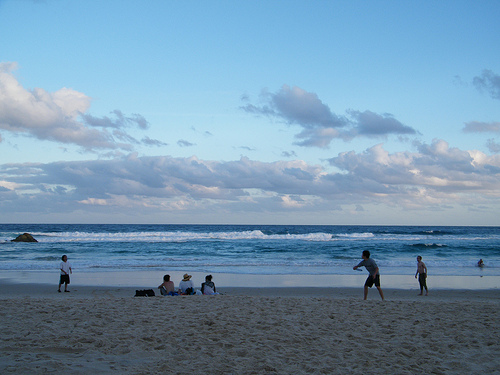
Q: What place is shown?
A: It is a beach.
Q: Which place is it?
A: It is a beach.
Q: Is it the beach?
A: Yes, it is the beach.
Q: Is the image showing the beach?
A: Yes, it is showing the beach.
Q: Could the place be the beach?
A: Yes, it is the beach.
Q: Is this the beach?
A: Yes, it is the beach.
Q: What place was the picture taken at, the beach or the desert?
A: It was taken at the beach.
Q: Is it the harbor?
A: No, it is the beach.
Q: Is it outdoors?
A: Yes, it is outdoors.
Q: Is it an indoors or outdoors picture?
A: It is outdoors.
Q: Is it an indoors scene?
A: No, it is outdoors.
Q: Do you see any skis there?
A: No, there are no skis.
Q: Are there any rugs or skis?
A: No, there are no skis or rugs.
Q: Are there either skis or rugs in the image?
A: No, there are no skis or rugs.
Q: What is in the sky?
A: The clouds are in the sky.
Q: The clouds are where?
A: The clouds are in the sky.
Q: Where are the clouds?
A: The clouds are in the sky.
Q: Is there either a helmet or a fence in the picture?
A: No, there are no fences or helmets.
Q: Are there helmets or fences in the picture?
A: No, there are no fences or helmets.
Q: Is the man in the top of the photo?
A: No, the man is in the bottom of the image.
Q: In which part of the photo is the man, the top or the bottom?
A: The man is in the bottom of the image.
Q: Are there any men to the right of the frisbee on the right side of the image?
A: Yes, there is a man to the right of the frisbee.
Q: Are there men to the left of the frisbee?
A: No, the man is to the right of the frisbee.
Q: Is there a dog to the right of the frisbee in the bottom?
A: No, there is a man to the right of the frisbee.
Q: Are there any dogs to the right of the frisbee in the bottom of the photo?
A: No, there is a man to the right of the frisbee.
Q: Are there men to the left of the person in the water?
A: Yes, there is a man to the left of the person.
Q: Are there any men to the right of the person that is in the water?
A: No, the man is to the left of the person.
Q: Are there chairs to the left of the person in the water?
A: No, there is a man to the left of the person.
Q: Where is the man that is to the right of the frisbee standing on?
A: The man is standing on the beach.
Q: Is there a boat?
A: No, there are no boats.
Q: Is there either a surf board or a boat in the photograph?
A: No, there are no boats or surfboards.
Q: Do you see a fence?
A: No, there are no fences.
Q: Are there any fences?
A: No, there are no fences.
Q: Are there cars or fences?
A: No, there are no fences or cars.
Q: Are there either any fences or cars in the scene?
A: No, there are no fences or cars.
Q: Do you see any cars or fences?
A: No, there are no fences or cars.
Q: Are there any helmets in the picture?
A: No, there are no helmets.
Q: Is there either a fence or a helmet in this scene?
A: No, there are no helmets or fences.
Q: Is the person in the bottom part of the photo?
A: Yes, the person is in the bottom of the image.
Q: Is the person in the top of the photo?
A: No, the person is in the bottom of the image.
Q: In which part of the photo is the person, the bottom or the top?
A: The person is in the bottom of the image.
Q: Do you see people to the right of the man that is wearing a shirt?
A: Yes, there is a person to the right of the man.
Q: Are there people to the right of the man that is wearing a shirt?
A: Yes, there is a person to the right of the man.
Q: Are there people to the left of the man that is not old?
A: No, the person is to the right of the man.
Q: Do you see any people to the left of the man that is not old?
A: No, the person is to the right of the man.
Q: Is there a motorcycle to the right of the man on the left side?
A: No, there is a person to the right of the man.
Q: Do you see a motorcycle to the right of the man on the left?
A: No, there is a person to the right of the man.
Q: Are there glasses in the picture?
A: No, there are no glasses.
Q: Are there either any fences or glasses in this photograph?
A: No, there are no glasses or fences.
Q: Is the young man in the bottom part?
A: Yes, the man is in the bottom of the image.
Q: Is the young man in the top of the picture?
A: No, the man is in the bottom of the image.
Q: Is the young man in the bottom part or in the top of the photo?
A: The man is in the bottom of the image.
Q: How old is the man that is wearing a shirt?
A: The man is young.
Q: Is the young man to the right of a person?
A: No, the man is to the left of a person.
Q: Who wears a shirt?
A: The man wears a shirt.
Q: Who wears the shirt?
A: The man wears a shirt.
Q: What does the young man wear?
A: The man wears a shirt.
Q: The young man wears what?
A: The man wears a shirt.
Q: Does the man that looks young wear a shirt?
A: Yes, the man wears a shirt.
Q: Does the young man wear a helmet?
A: No, the man wears a shirt.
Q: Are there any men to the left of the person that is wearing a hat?
A: Yes, there is a man to the left of the person.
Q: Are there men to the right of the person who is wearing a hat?
A: No, the man is to the left of the person.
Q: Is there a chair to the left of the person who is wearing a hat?
A: No, there is a man to the left of the person.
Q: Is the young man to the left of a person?
A: Yes, the man is to the left of a person.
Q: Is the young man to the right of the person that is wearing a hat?
A: No, the man is to the left of the person.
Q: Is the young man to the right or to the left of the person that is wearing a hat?
A: The man is to the left of the person.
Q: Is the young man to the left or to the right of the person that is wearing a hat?
A: The man is to the left of the person.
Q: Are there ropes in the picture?
A: No, there are no ropes.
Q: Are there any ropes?
A: No, there are no ropes.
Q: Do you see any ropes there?
A: No, there are no ropes.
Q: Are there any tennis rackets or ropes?
A: No, there are no ropes or tennis rackets.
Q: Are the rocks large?
A: Yes, the rocks are large.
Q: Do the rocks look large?
A: Yes, the rocks are large.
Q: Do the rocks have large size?
A: Yes, the rocks are large.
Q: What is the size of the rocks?
A: The rocks are large.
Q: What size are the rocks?
A: The rocks are large.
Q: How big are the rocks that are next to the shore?
A: The rocks are large.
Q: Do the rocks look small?
A: No, the rocks are large.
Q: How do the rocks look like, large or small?
A: The rocks are large.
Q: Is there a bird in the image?
A: No, there are no birds.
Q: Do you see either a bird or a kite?
A: No, there are no birds or kites.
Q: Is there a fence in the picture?
A: No, there are no fences.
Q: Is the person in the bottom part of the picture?
A: Yes, the person is in the bottom of the image.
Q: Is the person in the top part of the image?
A: No, the person is in the bottom of the image.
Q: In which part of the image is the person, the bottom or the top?
A: The person is in the bottom of the image.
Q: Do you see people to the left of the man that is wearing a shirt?
A: No, the person is to the right of the man.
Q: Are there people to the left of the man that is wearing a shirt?
A: No, the person is to the right of the man.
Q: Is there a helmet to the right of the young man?
A: No, there is a person to the right of the man.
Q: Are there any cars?
A: No, there are no cars.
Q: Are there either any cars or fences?
A: No, there are no cars or fences.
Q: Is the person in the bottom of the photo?
A: Yes, the person is in the bottom of the image.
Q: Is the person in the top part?
A: No, the person is in the bottom of the image.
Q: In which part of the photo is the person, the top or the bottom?
A: The person is in the bottom of the image.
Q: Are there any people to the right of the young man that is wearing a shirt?
A: Yes, there is a person to the right of the man.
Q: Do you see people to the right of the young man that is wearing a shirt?
A: Yes, there is a person to the right of the man.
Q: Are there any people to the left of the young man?
A: No, the person is to the right of the man.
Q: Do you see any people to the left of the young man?
A: No, the person is to the right of the man.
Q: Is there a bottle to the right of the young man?
A: No, there is a person to the right of the man.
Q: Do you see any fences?
A: No, there are no fences.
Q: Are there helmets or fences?
A: No, there are no fences or helmets.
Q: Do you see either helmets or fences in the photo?
A: No, there are no fences or helmets.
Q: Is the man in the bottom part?
A: Yes, the man is in the bottom of the image.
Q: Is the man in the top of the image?
A: No, the man is in the bottom of the image.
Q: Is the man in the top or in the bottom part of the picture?
A: The man is in the bottom of the image.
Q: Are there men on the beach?
A: Yes, there is a man on the beach.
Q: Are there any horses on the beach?
A: No, there is a man on the beach.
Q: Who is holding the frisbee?
A: The man is holding the frisbee.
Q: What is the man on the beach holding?
A: The man is holding the frisbee.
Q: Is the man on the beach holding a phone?
A: No, the man is holding the frisbee.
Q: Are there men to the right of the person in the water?
A: No, the man is to the left of the person.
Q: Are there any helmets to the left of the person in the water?
A: No, there is a man to the left of the person.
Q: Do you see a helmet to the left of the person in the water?
A: No, there is a man to the left of the person.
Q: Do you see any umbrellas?
A: No, there are no umbrellas.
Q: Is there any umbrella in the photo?
A: No, there are no umbrellas.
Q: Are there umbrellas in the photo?
A: No, there are no umbrellas.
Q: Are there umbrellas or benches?
A: No, there are no umbrellas or benches.